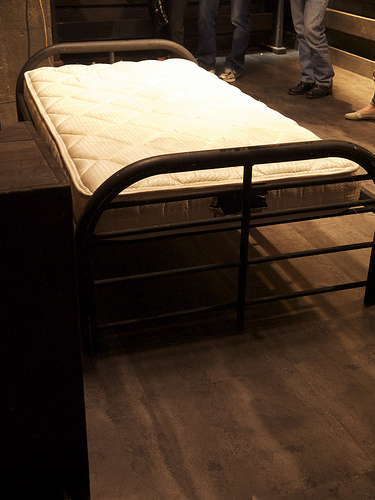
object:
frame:
[14, 38, 375, 358]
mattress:
[23, 54, 362, 240]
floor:
[1, 49, 374, 498]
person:
[192, 1, 253, 87]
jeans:
[196, 1, 247, 69]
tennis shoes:
[219, 64, 240, 86]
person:
[286, 1, 335, 100]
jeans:
[288, 2, 335, 88]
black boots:
[302, 79, 329, 102]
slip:
[355, 112, 360, 121]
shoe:
[342, 105, 373, 123]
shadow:
[64, 209, 335, 357]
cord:
[39, 4, 54, 68]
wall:
[0, 1, 53, 121]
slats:
[323, 2, 374, 43]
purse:
[147, 1, 174, 35]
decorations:
[157, 2, 171, 20]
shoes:
[285, 76, 314, 99]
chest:
[0, 118, 93, 500]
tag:
[210, 190, 265, 219]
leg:
[194, 5, 218, 67]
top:
[26, 58, 354, 193]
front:
[75, 139, 374, 351]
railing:
[74, 137, 374, 353]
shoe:
[306, 81, 332, 99]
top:
[2, 121, 69, 196]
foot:
[342, 104, 375, 123]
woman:
[343, 66, 374, 122]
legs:
[299, 2, 334, 90]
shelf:
[50, 2, 163, 62]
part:
[19, 44, 193, 115]